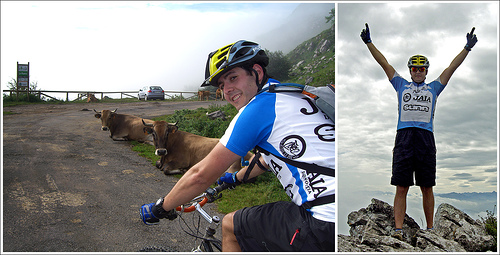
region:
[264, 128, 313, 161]
design on side of shirt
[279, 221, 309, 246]
red ink pen in pocket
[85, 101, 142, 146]
cow laying on road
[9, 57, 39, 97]
white and green wooden sign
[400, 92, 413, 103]
black design on front of shirt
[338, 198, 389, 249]
large grey rock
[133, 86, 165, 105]
silver car parked on side of road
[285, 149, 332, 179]
black backpack strap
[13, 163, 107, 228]
dirt on road pavement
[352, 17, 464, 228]
a man on top of rocks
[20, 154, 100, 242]
stains on the asphal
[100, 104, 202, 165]
two cows watching a biker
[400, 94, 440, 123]
black lettering on shirt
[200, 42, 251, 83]
a yellow and white helmet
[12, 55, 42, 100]
a sign on the edge on the street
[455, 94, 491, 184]
thick white cloud cover in the sky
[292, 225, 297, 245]
a red tag on the pocket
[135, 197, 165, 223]
blue and black glove on a hand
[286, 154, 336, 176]
a black stripe on a shirt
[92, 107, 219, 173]
two cows laying down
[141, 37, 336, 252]
a man riding a bike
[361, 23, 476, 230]
a man with his hands up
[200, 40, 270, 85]
a man's bike helmet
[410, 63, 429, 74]
a man's sunglasses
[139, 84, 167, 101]
a small grey car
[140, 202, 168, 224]
a man's left glove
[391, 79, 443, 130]
a man's blue shirt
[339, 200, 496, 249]
some large grey boulders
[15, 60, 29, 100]
a wood information sign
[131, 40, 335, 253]
Man is riding a bike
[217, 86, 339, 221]
bike shirt is white and blue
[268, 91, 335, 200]
Shirt has black letters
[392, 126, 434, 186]
Shorts are black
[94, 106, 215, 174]
There are two cows in background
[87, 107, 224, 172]
Cows are brown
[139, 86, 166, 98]
The car is silver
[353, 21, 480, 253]
Man is standing on rocks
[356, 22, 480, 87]
Man's hands are raised above head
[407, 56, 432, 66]
Man's helmet is yellow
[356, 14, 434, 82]
the sky is cloudy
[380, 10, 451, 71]
the sky is cloudy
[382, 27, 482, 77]
the sky is cloudy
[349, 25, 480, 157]
the sky is cloudy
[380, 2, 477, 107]
the sky is cloudy